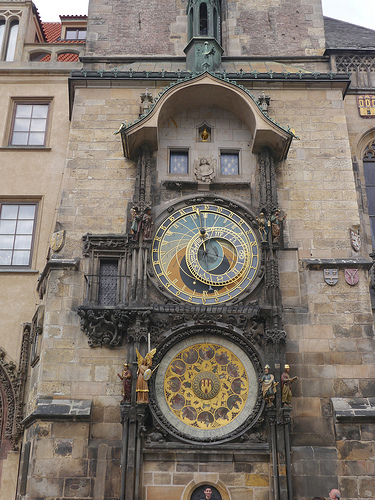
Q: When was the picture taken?
A: Daytime.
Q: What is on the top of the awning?
A: A weather vane.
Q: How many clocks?
A: Two.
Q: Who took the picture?
A: Man.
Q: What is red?
A: Rooftop.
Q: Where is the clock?
A: Middle of the tower.